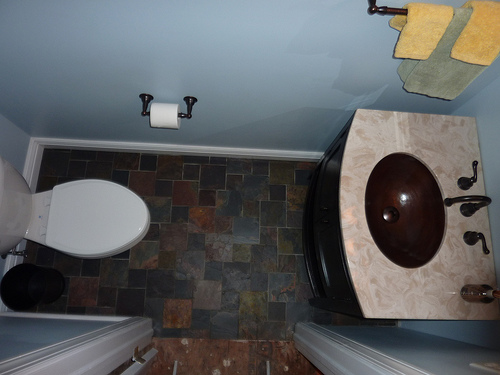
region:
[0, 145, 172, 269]
a white toilet in bathroom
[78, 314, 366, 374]
a open bathroom door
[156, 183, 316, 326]
tiles on the floor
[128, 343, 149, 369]
a silver hinge on frame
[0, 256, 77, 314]
a small black trash can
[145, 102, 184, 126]
toilet paper on a holder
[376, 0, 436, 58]
a yellow hand towel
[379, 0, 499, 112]
two yellow and one green towels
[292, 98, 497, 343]
a new bathroom vanity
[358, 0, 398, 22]
a modern towel rack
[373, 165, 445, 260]
basin of sink is brown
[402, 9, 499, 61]
two yellow towels hung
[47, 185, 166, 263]
toilet seat is down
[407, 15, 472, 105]
light green towel between yellow ones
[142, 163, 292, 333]
brick flooring between toilet and sink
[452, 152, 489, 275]
facets are dark in color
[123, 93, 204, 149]
toilet paper dispenser near toilet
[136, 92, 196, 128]
toilet holder is black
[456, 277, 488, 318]
clear glass to the left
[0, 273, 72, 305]
brown waster paper basket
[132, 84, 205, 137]
toilet paper on the wall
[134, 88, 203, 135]
white toilet paper on the wall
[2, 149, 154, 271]
toilet bowl in bathroom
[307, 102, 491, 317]
nice sink in bathroom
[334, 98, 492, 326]
porcelain sink in bathroom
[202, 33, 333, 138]
patch of blue wall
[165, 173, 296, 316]
multi colored tile floor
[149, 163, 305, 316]
neatly decorated tile floor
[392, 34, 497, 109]
wash towels in restroom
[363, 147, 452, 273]
nice oval sink area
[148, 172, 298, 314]
the bathroom floor is tiled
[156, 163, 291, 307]
the tiles are multi colored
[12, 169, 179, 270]
the lid is down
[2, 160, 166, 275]
the toilet is white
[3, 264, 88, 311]
the trash can is black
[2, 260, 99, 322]
the trash can is small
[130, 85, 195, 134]
the toilet paper is white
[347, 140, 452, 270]
the sink is brown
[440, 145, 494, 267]
the faucet is black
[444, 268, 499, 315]
a bottle on the counter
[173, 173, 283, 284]
this is a floor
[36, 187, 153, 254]
this is a toilet sink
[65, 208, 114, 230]
this is the lid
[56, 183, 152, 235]
the lid is covered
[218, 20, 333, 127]
this is the wall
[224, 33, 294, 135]
the wall is white in color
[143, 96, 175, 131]
this is a tissue paper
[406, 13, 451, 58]
this is a towel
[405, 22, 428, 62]
the towel is brown in color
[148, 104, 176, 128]
the tissue paper is brown in color